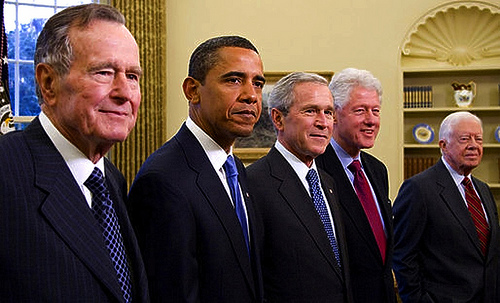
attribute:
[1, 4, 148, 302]
george bush — president, present, standing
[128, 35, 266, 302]
barack obama — president, present, standing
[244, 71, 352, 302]
george bush — present, standing, president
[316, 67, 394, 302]
bill clinton — present, standing, president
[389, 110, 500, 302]
jimmy carter — present, standing, president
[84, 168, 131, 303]
tie — checked, blue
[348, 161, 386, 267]
tie — maroon, red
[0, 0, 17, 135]
flag — present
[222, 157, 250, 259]
tie — blue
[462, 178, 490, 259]
tie — red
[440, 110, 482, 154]
hair — white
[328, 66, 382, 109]
hair — white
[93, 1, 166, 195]
drapes — gold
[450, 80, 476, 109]
pitcher — white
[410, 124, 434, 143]
plate — decorative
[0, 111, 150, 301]
suit — pin striped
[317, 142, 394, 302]
suit — black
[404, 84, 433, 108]
books — gold, blue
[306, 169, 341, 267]
tie — spotted